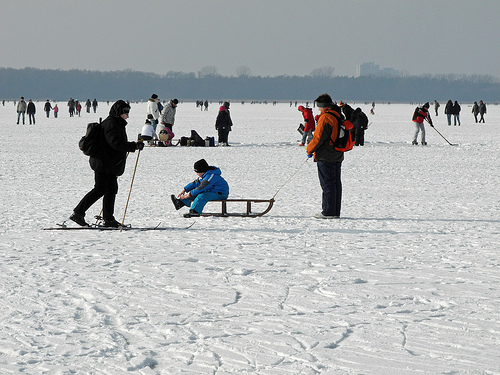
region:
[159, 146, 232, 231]
boy fixing his shoes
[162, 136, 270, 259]
boy fixing his shoes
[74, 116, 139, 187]
the jacket is black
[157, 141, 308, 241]
the is tying his shoe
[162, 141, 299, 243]
a boy sitting on a sled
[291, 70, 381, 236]
he is pulling the sled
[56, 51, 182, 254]
she is walking with her skis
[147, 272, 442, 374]
there are cracks in the snow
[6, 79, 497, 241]
people are walking on the snow and ice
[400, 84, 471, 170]
this person is holding a hockey stick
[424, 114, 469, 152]
this is a hockey stick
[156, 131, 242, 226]
a boy dressed in blue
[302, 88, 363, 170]
his jacket is orange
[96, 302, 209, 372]
The snow is white.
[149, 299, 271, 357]
The snow has cracks.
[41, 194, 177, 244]
The woman has on skies.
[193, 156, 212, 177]
The boy has on a hat.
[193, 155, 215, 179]
The hat is black.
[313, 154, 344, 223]
The woman's pants are dark in color.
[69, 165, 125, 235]
The woman's pants is dark in color.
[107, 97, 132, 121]
The woman has black hair.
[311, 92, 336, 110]
The woman has brown hair.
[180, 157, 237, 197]
The boy has on a blue coat.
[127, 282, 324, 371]
snow on the ground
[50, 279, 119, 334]
tracks in the snow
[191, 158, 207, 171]
black hat on boy's head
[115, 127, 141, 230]
ski pole in man's hand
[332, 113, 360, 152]
backpack on man's back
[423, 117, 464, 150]
hockey stick in man's hand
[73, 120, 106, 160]
black back pack on person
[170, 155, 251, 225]
little boy sitting on sled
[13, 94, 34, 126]
couple walking on snow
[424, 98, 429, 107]
black hat on person's head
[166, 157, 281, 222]
a child on a sled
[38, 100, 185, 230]
a person on skis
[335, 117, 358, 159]
a orange and black back pack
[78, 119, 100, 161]
a black back pack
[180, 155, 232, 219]
a person in a blue snow suite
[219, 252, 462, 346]
track in the snow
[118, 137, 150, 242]
a ski pole in left hand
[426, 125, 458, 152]
a wooden hockey stick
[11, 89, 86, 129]
a group of people walking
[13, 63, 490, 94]
gray trees in the distance